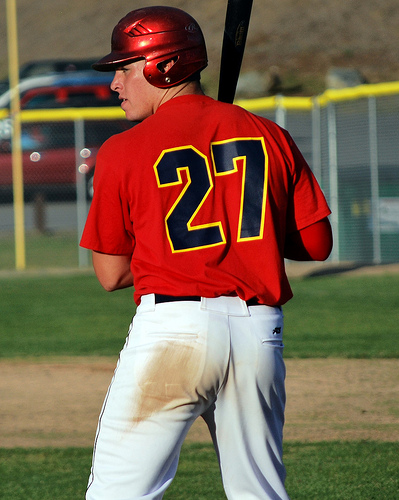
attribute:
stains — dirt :
[133, 342, 202, 424]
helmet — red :
[101, 5, 218, 87]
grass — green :
[289, 270, 392, 354]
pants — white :
[130, 300, 278, 470]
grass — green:
[0, 241, 397, 499]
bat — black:
[207, 14, 268, 124]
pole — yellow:
[5, 0, 30, 272]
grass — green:
[3, 443, 393, 494]